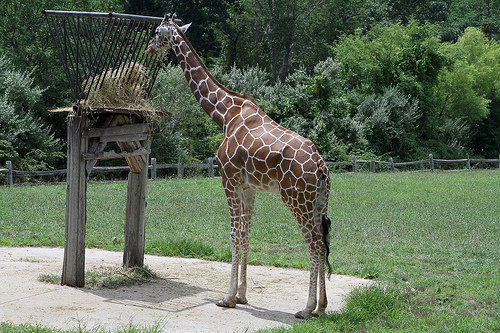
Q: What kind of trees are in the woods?
A: Green.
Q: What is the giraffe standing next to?
A: Food stand.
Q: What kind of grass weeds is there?
A: Green and brown.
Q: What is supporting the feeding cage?
A: A wooden stand.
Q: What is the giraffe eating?
A: Hay.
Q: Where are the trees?
A: On the other side of the fence.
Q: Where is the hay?
A: In the cage.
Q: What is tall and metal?
A: The feeder.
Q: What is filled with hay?
A: The feeder.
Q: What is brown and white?
A: The giraffe.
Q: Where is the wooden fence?
A: Behind the giraffe.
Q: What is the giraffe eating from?
A: A wooden feeder.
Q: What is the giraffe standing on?
A: Concrete slab.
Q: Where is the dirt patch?
A: On the ground.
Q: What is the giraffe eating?
A: Hay.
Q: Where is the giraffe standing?
A: On dirt.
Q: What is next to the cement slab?
A: Grass.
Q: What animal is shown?
A: A giraffe.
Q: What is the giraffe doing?
A: Eating.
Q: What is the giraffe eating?
A: Hay.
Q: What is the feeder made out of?
A: Metal.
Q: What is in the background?
A: Trees.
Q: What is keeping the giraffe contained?
A: A fence.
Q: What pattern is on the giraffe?
A: Spots.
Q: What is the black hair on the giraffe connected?
A: The tail.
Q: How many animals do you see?
A: One.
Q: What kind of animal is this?
A: A Giraffe.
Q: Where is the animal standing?
A: On on a concrete slab.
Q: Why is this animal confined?
A: Because it is in a zoo.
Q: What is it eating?
A: Hay.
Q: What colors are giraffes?
A: Yellow and brown.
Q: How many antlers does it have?
A: Two.